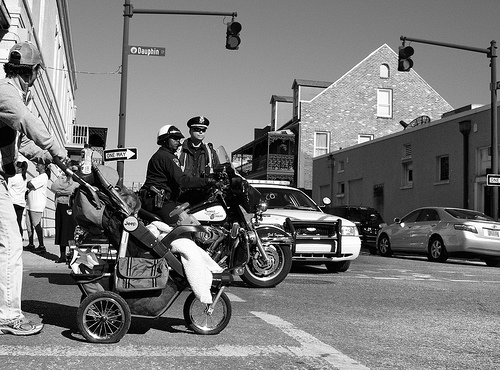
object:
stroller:
[43, 144, 232, 343]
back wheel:
[73, 288, 132, 344]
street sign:
[126, 44, 171, 55]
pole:
[114, 3, 131, 195]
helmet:
[154, 123, 185, 147]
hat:
[186, 114, 212, 129]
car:
[238, 174, 360, 272]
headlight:
[339, 224, 357, 238]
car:
[374, 203, 499, 263]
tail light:
[455, 222, 478, 236]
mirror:
[315, 195, 333, 208]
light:
[240, 178, 294, 187]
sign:
[102, 146, 141, 163]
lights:
[224, 35, 242, 50]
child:
[112, 181, 142, 219]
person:
[0, 40, 70, 343]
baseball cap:
[9, 41, 45, 72]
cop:
[182, 112, 219, 188]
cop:
[138, 123, 195, 226]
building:
[289, 40, 463, 196]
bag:
[110, 256, 170, 293]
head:
[3, 39, 50, 87]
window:
[374, 85, 397, 121]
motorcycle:
[67, 141, 295, 285]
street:
[2, 265, 497, 369]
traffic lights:
[226, 20, 241, 49]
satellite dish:
[396, 113, 433, 134]